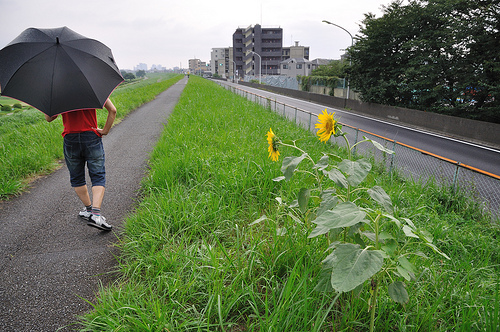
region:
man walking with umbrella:
[33, 75, 129, 248]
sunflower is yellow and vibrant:
[244, 124, 310, 185]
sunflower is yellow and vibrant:
[306, 95, 350, 157]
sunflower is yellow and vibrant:
[262, 122, 289, 165]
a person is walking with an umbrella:
[6, 8, 136, 251]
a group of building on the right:
[185, 32, 318, 92]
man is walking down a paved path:
[0, 20, 155, 251]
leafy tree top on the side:
[325, 35, 493, 113]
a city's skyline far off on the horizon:
[127, 60, 172, 74]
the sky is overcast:
[48, 2, 229, 29]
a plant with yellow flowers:
[258, 102, 399, 296]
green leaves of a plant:
[310, 161, 407, 301]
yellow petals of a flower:
[315, 105, 337, 150]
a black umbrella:
[0, 20, 127, 117]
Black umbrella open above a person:
[1, 25, 126, 115]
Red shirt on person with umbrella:
[56, 102, 99, 134]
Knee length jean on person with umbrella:
[62, 130, 106, 185]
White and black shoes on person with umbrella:
[78, 205, 113, 230]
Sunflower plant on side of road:
[264, 106, 452, 330]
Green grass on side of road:
[80, 70, 496, 330]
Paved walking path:
[1, 71, 189, 328]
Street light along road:
[248, 48, 263, 85]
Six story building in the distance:
[246, 25, 287, 82]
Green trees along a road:
[341, 0, 499, 112]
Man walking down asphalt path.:
[0, 24, 161, 276]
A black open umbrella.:
[3, 25, 129, 122]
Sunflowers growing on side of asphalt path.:
[257, 103, 420, 328]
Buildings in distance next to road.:
[191, 21, 336, 96]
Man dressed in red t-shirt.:
[51, 109, 108, 143]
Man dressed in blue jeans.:
[54, 131, 126, 193]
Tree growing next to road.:
[355, 12, 499, 129]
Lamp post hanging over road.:
[321, 11, 371, 103]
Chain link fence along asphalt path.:
[259, 87, 496, 208]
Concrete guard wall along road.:
[354, 94, 490, 145]